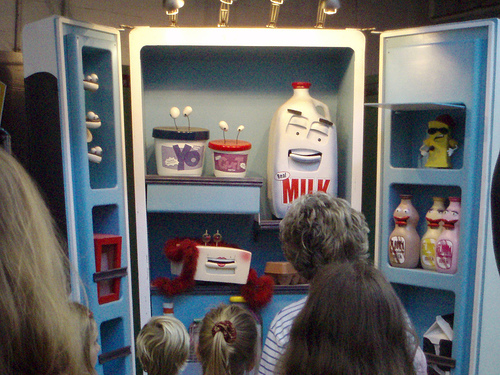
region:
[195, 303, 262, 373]
a girl with blonde hair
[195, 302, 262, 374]
a girl with blonde hair wearing a ponytail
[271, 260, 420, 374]
a girl with brown hair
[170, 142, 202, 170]
the word Yo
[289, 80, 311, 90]
a red top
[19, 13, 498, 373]
a blue refrigerator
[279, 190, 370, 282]
a lady with short blonde hair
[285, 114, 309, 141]
a white eye with a black pupil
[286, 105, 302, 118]
a black eyebrow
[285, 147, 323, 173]
a white mouth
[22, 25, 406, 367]
fake refrigerator in photo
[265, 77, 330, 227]
giant cartoonish milk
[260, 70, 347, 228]
milk carton with cartoony face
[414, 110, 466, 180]
bottle of mustard with face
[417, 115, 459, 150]
mustard wearing sunglasses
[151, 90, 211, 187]
white yogurt container with eyes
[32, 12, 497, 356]
fake blue refrigerator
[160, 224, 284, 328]
red scarf in refrigerator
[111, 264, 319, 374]
two children in photo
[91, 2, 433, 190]
refrigerator lit up by lights on top of refrigerator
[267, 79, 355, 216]
milk carton is white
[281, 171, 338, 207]
red lettering on milk carton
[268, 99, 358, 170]
milk carton has a face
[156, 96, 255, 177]
containers have eye balls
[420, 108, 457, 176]
yellow object wearing glasses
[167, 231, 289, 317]
toaster has arms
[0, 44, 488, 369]
people are looking in fridge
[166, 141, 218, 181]
the container says yo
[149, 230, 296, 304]
toaster's arms are red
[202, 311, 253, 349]
brown pony tail holder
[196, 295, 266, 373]
the blonde hair of the girl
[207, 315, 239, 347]
a red hair scrunchie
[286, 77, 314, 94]
a red bottle lid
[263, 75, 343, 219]
a large white jug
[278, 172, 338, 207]
red letters on the jug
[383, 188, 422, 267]
a brown bottle in the refrigerator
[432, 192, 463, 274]
a pink bottle in the refrigerator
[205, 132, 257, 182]
a white and purple container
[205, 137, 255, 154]
a red lid on the container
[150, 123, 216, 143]
a black lid on the container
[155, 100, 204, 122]
white marshmallows on stick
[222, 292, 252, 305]
yellow lid on bottle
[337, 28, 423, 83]
light on the blue door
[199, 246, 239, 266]
gray lid on white box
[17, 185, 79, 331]
gray and black long hair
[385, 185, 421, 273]
carton of chocolate milk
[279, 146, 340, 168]
mouth on the front of milk carton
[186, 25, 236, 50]
white edge of fridge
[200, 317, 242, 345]
red hair holder in girl's hair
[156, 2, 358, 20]
row of bulbs over fridge